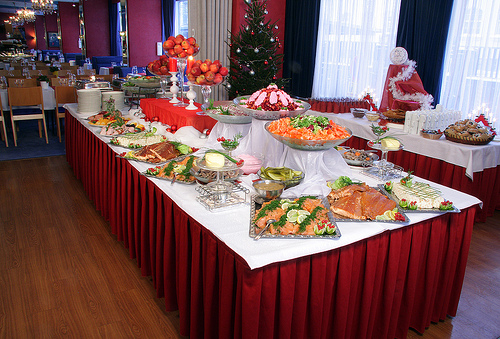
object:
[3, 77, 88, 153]
wooden chairs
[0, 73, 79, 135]
dinner tables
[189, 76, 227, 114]
bowl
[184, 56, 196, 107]
candle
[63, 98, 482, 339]
tablecloth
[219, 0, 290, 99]
christmas tree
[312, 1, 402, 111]
window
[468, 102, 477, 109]
ground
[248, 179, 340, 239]
tray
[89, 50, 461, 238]
food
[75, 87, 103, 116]
plates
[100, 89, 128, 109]
plates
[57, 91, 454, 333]
tab le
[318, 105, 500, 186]
tab le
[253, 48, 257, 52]
ornaments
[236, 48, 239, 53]
ornaments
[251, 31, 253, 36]
ornaments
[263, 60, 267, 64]
ornaments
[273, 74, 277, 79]
ornaments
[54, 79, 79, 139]
chair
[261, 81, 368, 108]
wall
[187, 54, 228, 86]
fruit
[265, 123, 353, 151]
bowl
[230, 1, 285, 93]
wall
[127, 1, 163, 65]
wall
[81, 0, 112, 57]
wall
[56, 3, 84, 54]
wall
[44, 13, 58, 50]
wall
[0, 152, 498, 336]
wooden floor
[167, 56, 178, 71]
candle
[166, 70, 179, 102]
candlestick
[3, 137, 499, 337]
floor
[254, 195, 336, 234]
food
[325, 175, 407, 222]
food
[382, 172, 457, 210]
food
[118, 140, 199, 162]
food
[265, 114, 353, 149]
food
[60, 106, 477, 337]
carpet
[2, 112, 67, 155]
hardwood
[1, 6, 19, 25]
lights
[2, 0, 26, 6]
ceiling